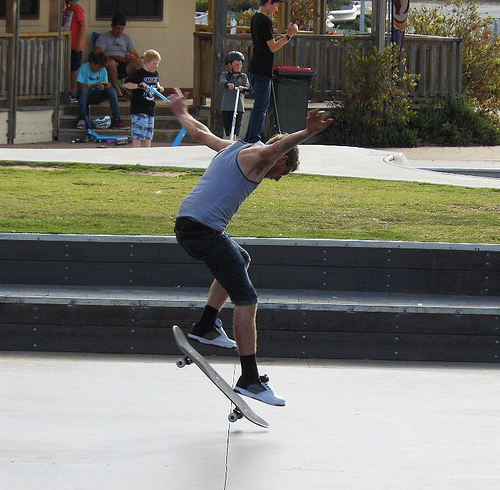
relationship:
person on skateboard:
[164, 82, 334, 407] [162, 314, 273, 432]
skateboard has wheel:
[162, 314, 273, 432] [227, 412, 239, 423]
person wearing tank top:
[164, 82, 334, 407] [169, 138, 275, 231]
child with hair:
[120, 47, 171, 147] [137, 47, 158, 61]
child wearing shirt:
[120, 47, 171, 147] [124, 70, 166, 117]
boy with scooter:
[216, 49, 252, 140] [220, 85, 248, 138]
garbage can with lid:
[272, 63, 314, 143] [276, 60, 318, 74]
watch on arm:
[282, 29, 295, 47] [255, 19, 303, 50]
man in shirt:
[93, 15, 148, 77] [94, 29, 141, 61]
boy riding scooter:
[216, 49, 252, 140] [220, 85, 248, 138]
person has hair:
[164, 82, 334, 407] [271, 125, 305, 175]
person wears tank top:
[164, 82, 334, 407] [169, 138, 275, 231]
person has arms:
[164, 82, 334, 407] [161, 85, 337, 172]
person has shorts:
[164, 82, 334, 407] [171, 214, 270, 310]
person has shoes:
[164, 82, 334, 407] [186, 313, 289, 408]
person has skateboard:
[164, 82, 334, 407] [162, 314, 273, 432]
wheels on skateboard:
[170, 356, 188, 370] [162, 314, 273, 432]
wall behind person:
[3, 230, 499, 367] [164, 82, 334, 407]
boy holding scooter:
[216, 49, 252, 140] [220, 85, 248, 138]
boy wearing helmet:
[216, 49, 252, 140] [222, 50, 244, 64]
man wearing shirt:
[242, 5, 293, 142] [242, 11, 283, 74]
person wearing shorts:
[164, 82, 334, 407] [171, 214, 270, 310]